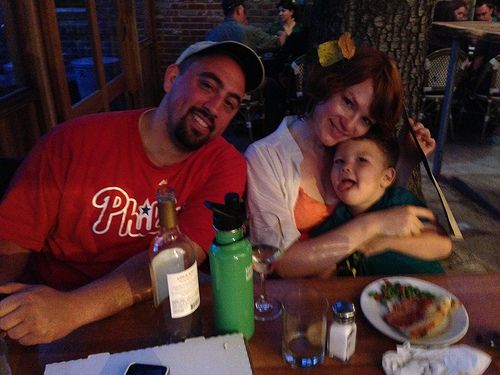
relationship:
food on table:
[367, 277, 459, 339] [0, 272, 499, 373]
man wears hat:
[0, 34, 272, 346] [154, 53, 284, 113]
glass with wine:
[239, 207, 288, 327] [248, 240, 285, 277]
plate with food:
[360, 277, 469, 346] [378, 278, 448, 335]